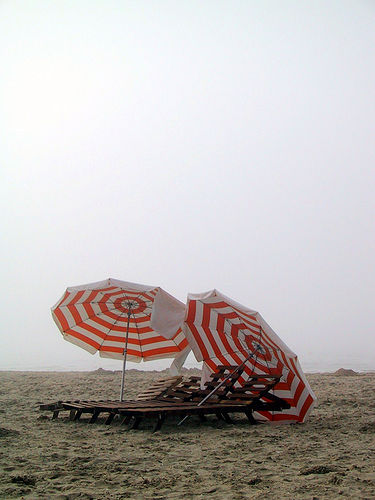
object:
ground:
[0, 367, 375, 500]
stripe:
[64, 328, 103, 351]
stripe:
[76, 321, 108, 341]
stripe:
[89, 315, 113, 330]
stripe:
[102, 310, 122, 321]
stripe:
[142, 346, 180, 358]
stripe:
[186, 322, 211, 360]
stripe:
[272, 413, 300, 421]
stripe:
[215, 330, 234, 354]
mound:
[335, 367, 357, 375]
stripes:
[66, 290, 86, 306]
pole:
[120, 311, 133, 402]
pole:
[176, 346, 261, 427]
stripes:
[57, 290, 71, 309]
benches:
[61, 376, 203, 425]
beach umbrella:
[50, 278, 192, 422]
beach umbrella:
[177, 287, 318, 428]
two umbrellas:
[50, 277, 318, 427]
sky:
[0, 0, 375, 372]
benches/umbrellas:
[40, 375, 185, 423]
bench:
[119, 373, 292, 435]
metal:
[58, 286, 182, 359]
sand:
[0, 368, 375, 500]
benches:
[91, 366, 245, 432]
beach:
[0, 366, 374, 499]